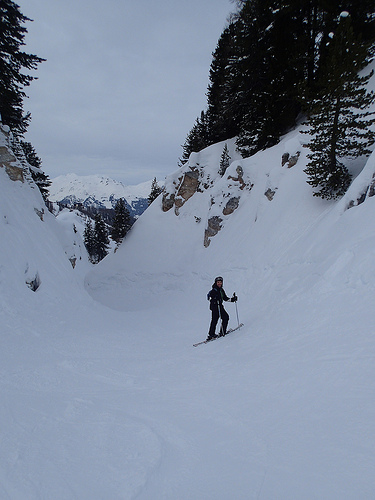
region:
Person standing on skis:
[183, 262, 251, 356]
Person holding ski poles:
[181, 266, 249, 345]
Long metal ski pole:
[226, 285, 241, 332]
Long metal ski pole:
[211, 292, 226, 338]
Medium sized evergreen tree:
[105, 191, 135, 251]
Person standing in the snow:
[182, 261, 249, 357]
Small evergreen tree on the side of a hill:
[215, 137, 235, 183]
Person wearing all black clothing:
[186, 271, 251, 360]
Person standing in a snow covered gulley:
[185, 262, 260, 363]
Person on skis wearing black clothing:
[189, 268, 262, 354]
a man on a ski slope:
[180, 272, 263, 349]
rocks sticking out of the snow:
[156, 154, 252, 247]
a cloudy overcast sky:
[23, 6, 210, 179]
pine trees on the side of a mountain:
[210, 17, 313, 175]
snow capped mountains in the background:
[40, 170, 165, 232]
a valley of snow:
[20, 186, 203, 356]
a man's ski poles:
[213, 291, 253, 339]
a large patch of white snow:
[5, 233, 370, 497]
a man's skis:
[192, 320, 247, 350]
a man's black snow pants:
[204, 305, 232, 339]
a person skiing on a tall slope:
[173, 263, 260, 350]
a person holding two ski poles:
[190, 276, 259, 351]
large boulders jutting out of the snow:
[176, 167, 239, 221]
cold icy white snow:
[98, 396, 244, 456]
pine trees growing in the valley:
[82, 199, 133, 246]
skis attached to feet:
[191, 340, 217, 345]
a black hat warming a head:
[213, 274, 225, 280]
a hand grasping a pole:
[230, 295, 238, 300]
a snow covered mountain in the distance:
[55, 172, 143, 195]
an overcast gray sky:
[58, 50, 149, 115]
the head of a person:
[214, 274, 225, 288]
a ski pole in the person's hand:
[232, 290, 242, 332]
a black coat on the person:
[204, 286, 234, 313]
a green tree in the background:
[107, 196, 132, 242]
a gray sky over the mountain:
[0, 0, 247, 187]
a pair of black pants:
[205, 304, 229, 339]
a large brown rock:
[174, 169, 200, 211]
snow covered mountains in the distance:
[40, 170, 166, 203]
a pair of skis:
[189, 321, 245, 351]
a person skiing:
[190, 273, 243, 349]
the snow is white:
[105, 336, 192, 427]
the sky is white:
[69, 31, 147, 112]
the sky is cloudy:
[55, 18, 142, 116]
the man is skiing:
[182, 260, 262, 359]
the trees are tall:
[226, 26, 296, 132]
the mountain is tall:
[55, 151, 135, 227]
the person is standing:
[188, 270, 261, 346]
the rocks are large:
[147, 147, 222, 235]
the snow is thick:
[21, 260, 111, 383]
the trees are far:
[77, 161, 137, 291]